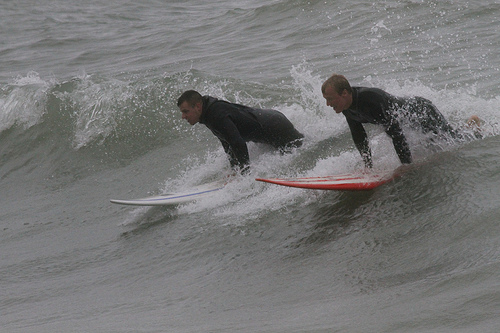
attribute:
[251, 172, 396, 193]
surfboard — red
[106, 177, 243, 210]
surfboard — white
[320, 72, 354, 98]
hair — blond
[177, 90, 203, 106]
hair — dark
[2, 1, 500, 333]
ocean — choppy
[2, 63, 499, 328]
wave — small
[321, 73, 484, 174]
surfer — giving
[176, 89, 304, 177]
man — wet, on vacation, careful, getting exercise, surfing, enjoying, close to beach, testing, out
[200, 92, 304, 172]
wet suit — black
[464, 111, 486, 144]
foot — bare